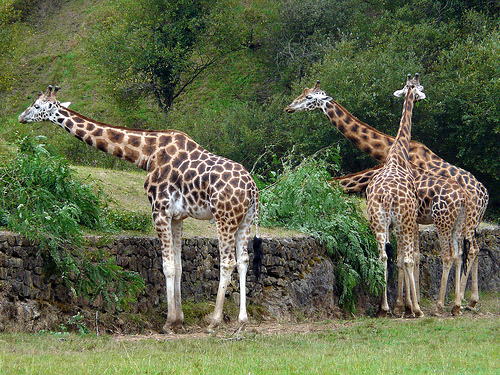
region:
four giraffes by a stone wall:
[7, 43, 499, 338]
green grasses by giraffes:
[18, 351, 478, 373]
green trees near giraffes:
[19, 6, 489, 72]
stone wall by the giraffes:
[260, 237, 337, 314]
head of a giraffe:
[12, 72, 81, 130]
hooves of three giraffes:
[377, 296, 494, 323]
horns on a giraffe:
[402, 69, 420, 85]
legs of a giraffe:
[141, 215, 264, 337]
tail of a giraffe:
[251, 181, 266, 291]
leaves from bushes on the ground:
[298, 164, 371, 294]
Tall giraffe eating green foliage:
[13, 80, 267, 339]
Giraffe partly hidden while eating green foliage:
[315, 162, 472, 315]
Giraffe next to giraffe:
[362, 70, 428, 317]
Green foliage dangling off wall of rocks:
[0, 134, 153, 307]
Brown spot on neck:
[55, 106, 73, 118]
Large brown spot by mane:
[107, 125, 124, 142]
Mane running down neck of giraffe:
[58, 100, 178, 140]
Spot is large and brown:
[347, 118, 361, 133]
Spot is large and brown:
[448, 165, 460, 177]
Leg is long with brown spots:
[152, 210, 179, 335]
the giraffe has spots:
[84, 112, 240, 236]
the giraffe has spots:
[7, 67, 376, 312]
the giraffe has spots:
[61, 91, 274, 351]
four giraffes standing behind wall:
[24, 67, 484, 323]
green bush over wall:
[262, 153, 370, 250]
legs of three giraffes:
[372, 238, 487, 318]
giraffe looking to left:
[12, 74, 107, 146]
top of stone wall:
[111, 229, 148, 264]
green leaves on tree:
[112, 8, 226, 65]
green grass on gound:
[277, 335, 411, 366]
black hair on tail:
[245, 229, 271, 284]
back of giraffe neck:
[392, 100, 410, 156]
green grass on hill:
[90, 165, 126, 195]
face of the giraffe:
[18, 95, 73, 135]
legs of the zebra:
[213, 251, 290, 321]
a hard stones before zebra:
[36, 220, 372, 325]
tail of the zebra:
[250, 202, 273, 246]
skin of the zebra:
[161, 144, 220, 194]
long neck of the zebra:
[400, 72, 425, 177]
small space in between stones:
[266, 265, 287, 289]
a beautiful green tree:
[258, 157, 402, 339]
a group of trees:
[107, 35, 492, 168]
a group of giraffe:
[31, 70, 488, 310]